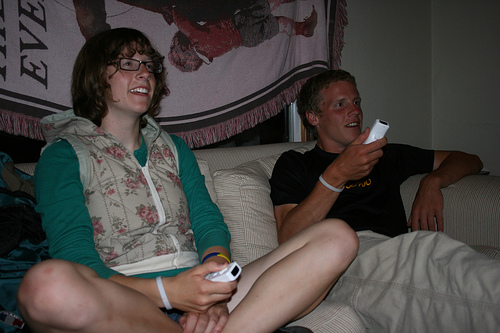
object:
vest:
[42, 107, 206, 274]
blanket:
[324, 225, 499, 332]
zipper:
[131, 158, 184, 251]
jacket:
[33, 121, 233, 281]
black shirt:
[268, 140, 438, 240]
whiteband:
[318, 168, 347, 201]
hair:
[295, 67, 357, 133]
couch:
[0, 133, 499, 329]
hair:
[62, 23, 172, 127]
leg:
[223, 216, 360, 331]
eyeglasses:
[93, 55, 162, 74]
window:
[195, 103, 299, 149]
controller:
[360, 117, 397, 157]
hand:
[323, 124, 393, 191]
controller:
[196, 260, 246, 284]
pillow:
[192, 154, 284, 265]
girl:
[7, 26, 359, 331]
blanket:
[3, 2, 352, 150]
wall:
[0, 0, 499, 162]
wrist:
[326, 161, 352, 186]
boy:
[269, 64, 499, 333]